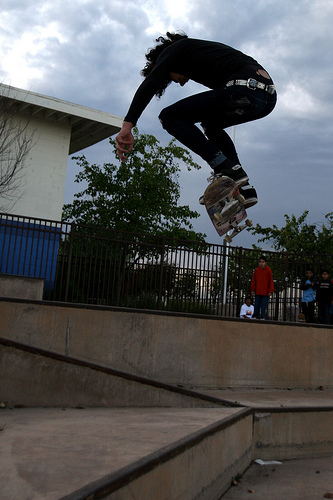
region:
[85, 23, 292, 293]
a skateboarder is getting air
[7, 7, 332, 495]
the boy is at a skate park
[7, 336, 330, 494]
the skate park has rails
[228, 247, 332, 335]
boys are watching the skateboarder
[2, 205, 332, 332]
a black wrought iron fence is around the park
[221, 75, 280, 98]
the skateboarder has a silver belt on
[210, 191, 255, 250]
white trucks and wheels are on the skateboard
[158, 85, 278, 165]
the black jeans are rolled up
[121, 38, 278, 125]
a black long sleeve shirt is on the skater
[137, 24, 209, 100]
the boy has curly black hair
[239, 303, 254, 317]
white top man is wearing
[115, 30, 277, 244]
boy skateboarding through the air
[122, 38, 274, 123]
black top skateboarder is wearing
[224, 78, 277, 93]
white belt holding pants up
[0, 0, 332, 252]
blue sky with white clouds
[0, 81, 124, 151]
white roof of the building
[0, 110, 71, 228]
white wall of the building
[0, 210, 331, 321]
black roth iron fence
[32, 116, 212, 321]
tall tree near the skateboarder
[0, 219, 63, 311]
blue part of the wall of the building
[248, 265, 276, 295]
red jacket on the kid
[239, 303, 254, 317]
white shirt on the kid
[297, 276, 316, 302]
blue and black jacket on the kid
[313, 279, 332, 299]
black shirt with white letters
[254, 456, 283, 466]
white paper on the floor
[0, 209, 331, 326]
black metal fence by the kids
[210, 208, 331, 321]
green trees near the kids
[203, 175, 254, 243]
skateboard under the skateboarder's feet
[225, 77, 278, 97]
white belt in the black pants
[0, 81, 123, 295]
white and blue building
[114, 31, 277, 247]
a skateboarder performing a trick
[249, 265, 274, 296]
boy wearing a red sweater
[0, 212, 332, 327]
a black metal fence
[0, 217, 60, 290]
a blue wall on a white building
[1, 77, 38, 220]
tree branches without any foliage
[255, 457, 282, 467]
a white paper on the corner of a step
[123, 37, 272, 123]
man wearing a black long sleeve shirt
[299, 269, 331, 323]
two boys standing close together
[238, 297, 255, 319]
a boy sitting on the ground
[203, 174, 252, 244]
a skateboard up in the air